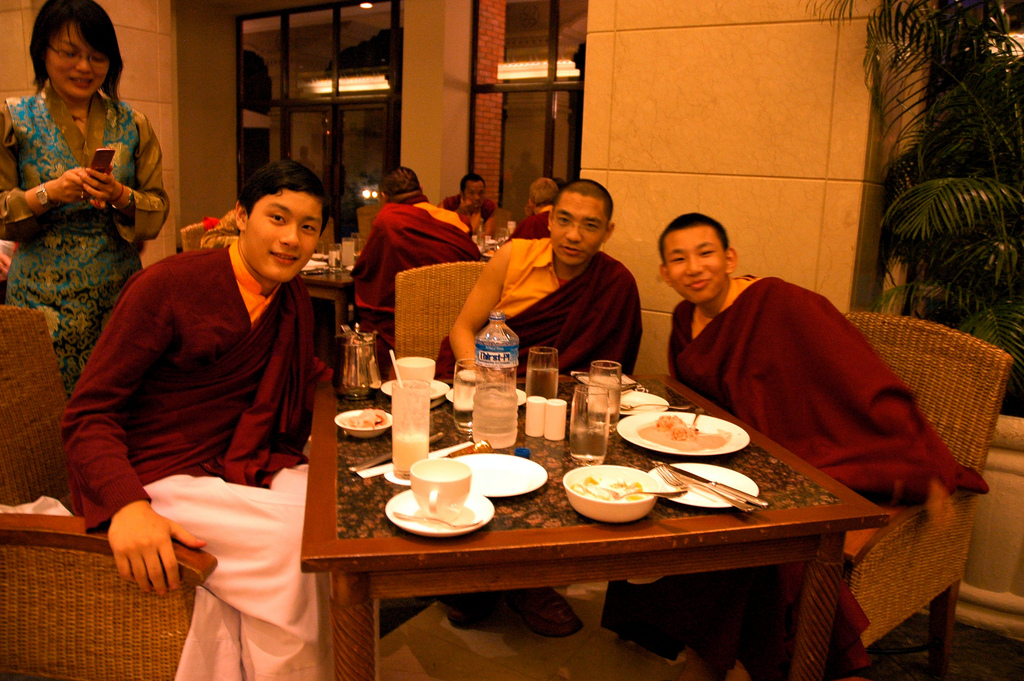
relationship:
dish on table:
[383, 487, 492, 536] [298, 370, 887, 678]